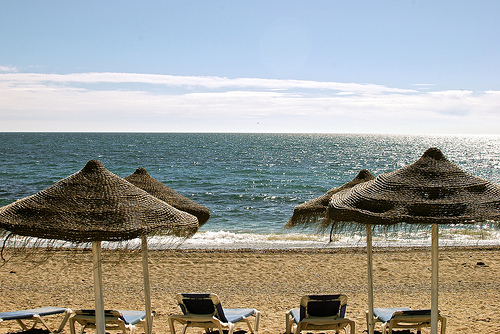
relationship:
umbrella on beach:
[0, 159, 200, 333] [2, 242, 496, 332]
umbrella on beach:
[120, 166, 210, 225] [2, 242, 496, 332]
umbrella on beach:
[322, 146, 500, 334] [2, 242, 496, 332]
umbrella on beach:
[283, 170, 379, 333] [2, 242, 496, 332]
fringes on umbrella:
[2, 228, 191, 258] [2, 187, 202, 264]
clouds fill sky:
[116, 91, 329, 133] [111, 93, 351, 135]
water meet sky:
[174, 133, 330, 154] [178, 116, 334, 136]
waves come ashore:
[0, 226, 500, 249] [213, 239, 313, 270]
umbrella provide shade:
[322, 146, 500, 334] [342, 314, 391, 332]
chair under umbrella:
[362, 301, 435, 332] [308, 160, 458, 212]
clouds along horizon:
[0, 65, 22, 73] [7, 115, 495, 141]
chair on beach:
[75, 298, 145, 332] [71, 287, 154, 316]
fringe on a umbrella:
[318, 208, 497, 241] [327, 146, 497, 226]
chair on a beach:
[365, 308, 448, 334] [2, 242, 496, 332]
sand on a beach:
[4, 244, 496, 326] [4, 220, 490, 327]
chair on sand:
[365, 308, 448, 334] [4, 244, 496, 326]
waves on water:
[0, 226, 500, 249] [0, 131, 495, 231]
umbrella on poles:
[322, 146, 500, 334] [363, 223, 439, 330]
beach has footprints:
[150, 239, 499, 304] [196, 255, 297, 283]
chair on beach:
[2, 305, 76, 333] [156, 241, 347, 299]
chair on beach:
[75, 307, 145, 332] [156, 241, 347, 299]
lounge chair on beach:
[166, 291, 260, 334] [156, 241, 347, 299]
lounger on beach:
[282, 282, 359, 332] [156, 241, 347, 299]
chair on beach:
[365, 308, 448, 334] [156, 241, 347, 299]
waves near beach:
[211, 226, 311, 246] [202, 242, 351, 290]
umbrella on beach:
[322, 144, 496, 222] [215, 251, 340, 297]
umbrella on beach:
[283, 191, 353, 228] [215, 251, 340, 297]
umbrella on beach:
[4, 166, 200, 239] [215, 251, 340, 297]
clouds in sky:
[233, 77, 498, 129] [2, 4, 498, 77]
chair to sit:
[365, 308, 448, 334] [373, 305, 414, 317]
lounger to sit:
[282, 291, 356, 333] [286, 302, 300, 323]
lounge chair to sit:
[166, 291, 260, 334] [224, 302, 258, 325]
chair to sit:
[75, 307, 145, 332] [121, 305, 151, 332]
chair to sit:
[2, 300, 76, 330] [30, 300, 64, 314]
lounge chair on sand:
[159, 285, 266, 332] [62, 258, 367, 332]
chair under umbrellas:
[365, 308, 448, 334] [12, 144, 499, 258]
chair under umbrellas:
[365, 308, 448, 334] [8, 142, 498, 249]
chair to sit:
[2, 305, 76, 333] [32, 300, 70, 316]